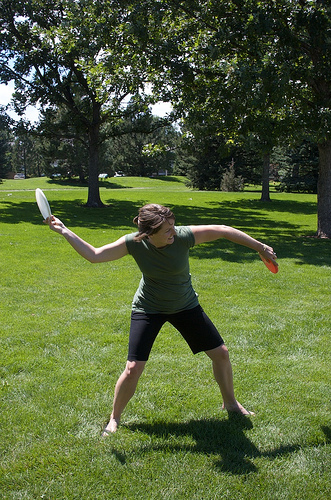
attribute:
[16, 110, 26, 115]
leaf — green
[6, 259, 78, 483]
grass — green